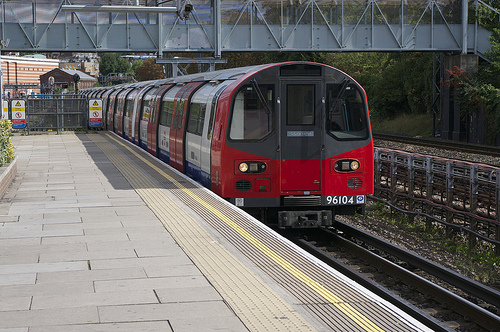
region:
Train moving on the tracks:
[78, 62, 498, 331]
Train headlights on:
[233, 160, 363, 170]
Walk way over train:
[0, 0, 499, 54]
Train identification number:
[325, 194, 354, 204]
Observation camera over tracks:
[181, 2, 195, 17]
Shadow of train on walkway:
[74, 132, 201, 195]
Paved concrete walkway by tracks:
[0, 130, 247, 330]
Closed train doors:
[134, 79, 206, 174]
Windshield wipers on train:
[239, 78, 367, 136]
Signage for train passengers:
[86, 97, 103, 125]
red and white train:
[82, 62, 377, 227]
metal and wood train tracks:
[315, 226, 495, 331]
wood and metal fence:
[23, 95, 90, 132]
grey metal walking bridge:
[2, 4, 497, 60]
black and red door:
[282, 79, 322, 197]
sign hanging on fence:
[88, 99, 103, 128]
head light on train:
[239, 161, 264, 176]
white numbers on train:
[326, 195, 353, 206]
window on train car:
[187, 102, 205, 136]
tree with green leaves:
[335, 49, 431, 121]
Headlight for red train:
[236, 155, 261, 175]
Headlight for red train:
[328, 153, 362, 172]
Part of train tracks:
[361, 243, 405, 285]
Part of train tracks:
[439, 284, 478, 321]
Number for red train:
[319, 192, 369, 207]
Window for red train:
[225, 78, 275, 146]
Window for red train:
[277, 75, 317, 140]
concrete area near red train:
[58, 213, 144, 270]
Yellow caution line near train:
[227, 221, 283, 276]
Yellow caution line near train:
[316, 280, 368, 329]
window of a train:
[237, 88, 361, 135]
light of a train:
[229, 146, 276, 181]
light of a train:
[329, 151, 367, 173]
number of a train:
[309, 189, 369, 213]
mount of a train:
[273, 205, 335, 235]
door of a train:
[202, 83, 232, 181]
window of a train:
[177, 79, 208, 133]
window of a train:
[153, 96, 180, 118]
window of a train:
[112, 95, 154, 115]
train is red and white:
[86, 60, 378, 213]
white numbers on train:
[315, 186, 360, 206]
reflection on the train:
[90, 67, 287, 195]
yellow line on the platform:
[105, 125, 379, 328]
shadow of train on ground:
[70, 122, 204, 205]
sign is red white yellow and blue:
[7, 94, 38, 134]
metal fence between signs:
[18, 94, 92, 128]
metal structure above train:
[1, 5, 481, 68]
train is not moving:
[81, 63, 381, 231]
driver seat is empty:
[321, 111, 344, 139]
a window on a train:
[225, 78, 266, 138]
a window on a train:
[321, 76, 371, 141]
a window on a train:
[281, 78, 316, 127]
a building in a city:
[70, 49, 103, 80]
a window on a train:
[180, 96, 205, 136]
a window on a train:
[135, 95, 151, 120]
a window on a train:
[117, 96, 132, 118]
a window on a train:
[107, 91, 125, 119]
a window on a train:
[98, 92, 111, 117]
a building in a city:
[8, 57, 65, 94]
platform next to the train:
[9, 130, 363, 330]